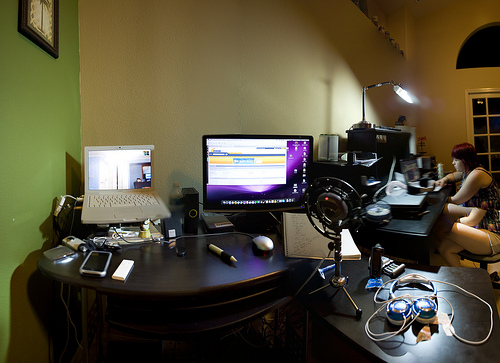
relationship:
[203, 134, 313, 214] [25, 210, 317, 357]
monitor on table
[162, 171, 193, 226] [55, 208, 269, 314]
bottle in back of desk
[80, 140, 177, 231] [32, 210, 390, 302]
laptop on desk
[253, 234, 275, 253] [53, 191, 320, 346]
computer mouse on desk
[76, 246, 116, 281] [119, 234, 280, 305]
smartphone on desk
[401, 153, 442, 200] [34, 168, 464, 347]
laptop on desk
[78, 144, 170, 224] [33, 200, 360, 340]
laptop on table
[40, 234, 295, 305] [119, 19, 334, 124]
table against wall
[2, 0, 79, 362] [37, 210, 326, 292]
wall beside table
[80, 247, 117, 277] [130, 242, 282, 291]
cellphone on table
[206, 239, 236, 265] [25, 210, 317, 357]
pen on table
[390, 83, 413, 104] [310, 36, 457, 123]
light on background